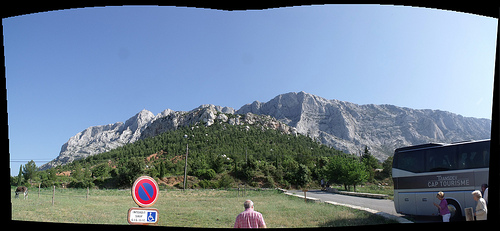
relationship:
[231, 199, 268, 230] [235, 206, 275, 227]
man wears purple shirt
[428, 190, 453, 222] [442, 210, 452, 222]
person wears pants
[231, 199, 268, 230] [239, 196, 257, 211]
man has hair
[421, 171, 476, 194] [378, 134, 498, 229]
writing on bus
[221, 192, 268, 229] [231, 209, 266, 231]
man wears purple shirt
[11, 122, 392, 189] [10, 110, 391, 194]
hill covered in forest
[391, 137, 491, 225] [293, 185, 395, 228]
bus stopped on road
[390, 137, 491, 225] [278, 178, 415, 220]
bus traveled on road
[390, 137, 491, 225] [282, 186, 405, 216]
bus stopped on road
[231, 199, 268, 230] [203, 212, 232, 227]
man walking on grass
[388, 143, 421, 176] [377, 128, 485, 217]
window on bus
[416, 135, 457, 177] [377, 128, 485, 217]
window on bus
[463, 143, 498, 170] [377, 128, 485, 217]
window on bus